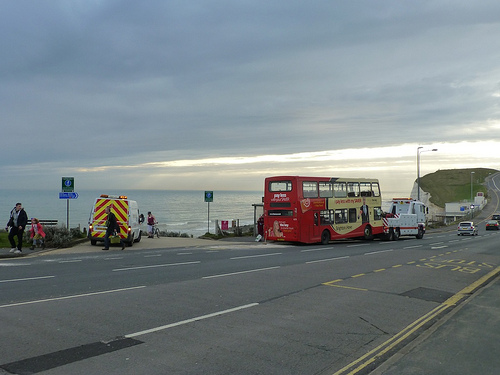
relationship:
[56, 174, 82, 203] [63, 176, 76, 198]
sign for traffic information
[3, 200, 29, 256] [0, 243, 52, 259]
man walking on sidewalk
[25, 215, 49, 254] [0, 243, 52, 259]
child walking on sidewalk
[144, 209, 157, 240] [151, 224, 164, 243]
man with bicycle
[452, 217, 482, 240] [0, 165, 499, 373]
car on road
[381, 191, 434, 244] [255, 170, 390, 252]
tow truck towing bus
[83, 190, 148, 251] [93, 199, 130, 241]
van has doors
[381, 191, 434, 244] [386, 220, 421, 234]
tow truck has stripe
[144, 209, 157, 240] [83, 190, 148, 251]
person standing in front of van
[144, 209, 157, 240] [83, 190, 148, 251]
person in front of van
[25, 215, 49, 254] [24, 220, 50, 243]
girl has jacket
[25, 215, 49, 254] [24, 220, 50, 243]
girl wearing jacket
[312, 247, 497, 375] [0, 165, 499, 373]
lines are in road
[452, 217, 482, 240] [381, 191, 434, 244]
car in front of tow truck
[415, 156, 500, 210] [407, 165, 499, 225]
grass above cliff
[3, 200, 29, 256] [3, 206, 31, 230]
man in jacket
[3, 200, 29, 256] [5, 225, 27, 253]
man in pants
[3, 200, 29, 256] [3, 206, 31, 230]
man wearing jacket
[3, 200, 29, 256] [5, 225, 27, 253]
man wearing pants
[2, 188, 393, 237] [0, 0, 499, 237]
water in background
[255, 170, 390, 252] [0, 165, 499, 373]
bus parked on road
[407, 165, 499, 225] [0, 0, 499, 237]
cliff in background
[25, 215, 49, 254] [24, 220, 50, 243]
child has jacket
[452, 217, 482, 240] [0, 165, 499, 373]
car drives on road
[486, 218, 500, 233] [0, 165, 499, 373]
car drives on road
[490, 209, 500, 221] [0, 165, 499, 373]
car drives on road